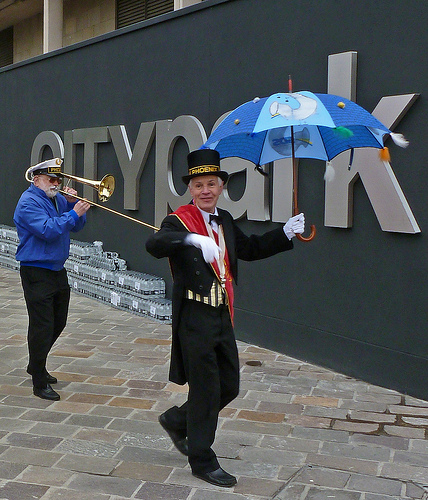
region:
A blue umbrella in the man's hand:
[203, 90, 387, 239]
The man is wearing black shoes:
[159, 402, 232, 483]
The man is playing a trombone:
[25, 163, 166, 229]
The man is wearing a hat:
[30, 157, 64, 175]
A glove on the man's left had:
[285, 211, 306, 234]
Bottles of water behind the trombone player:
[3, 224, 171, 318]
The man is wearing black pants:
[175, 304, 241, 467]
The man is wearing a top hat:
[180, 149, 229, 177]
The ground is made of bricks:
[0, 264, 426, 498]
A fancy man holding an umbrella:
[146, 82, 393, 489]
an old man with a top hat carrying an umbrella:
[138, 71, 411, 489]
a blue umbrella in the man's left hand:
[196, 67, 410, 246]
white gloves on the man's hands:
[184, 212, 308, 265]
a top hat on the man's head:
[180, 148, 231, 183]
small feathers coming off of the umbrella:
[312, 121, 410, 187]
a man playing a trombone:
[12, 155, 170, 404]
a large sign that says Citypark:
[25, 53, 425, 237]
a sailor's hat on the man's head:
[25, 156, 67, 178]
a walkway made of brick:
[1, 263, 427, 498]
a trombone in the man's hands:
[22, 165, 163, 231]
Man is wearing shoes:
[154, 409, 237, 486]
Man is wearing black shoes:
[155, 409, 242, 487]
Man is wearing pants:
[163, 297, 243, 476]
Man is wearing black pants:
[161, 295, 243, 474]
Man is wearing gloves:
[184, 211, 309, 261]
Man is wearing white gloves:
[180, 210, 305, 261]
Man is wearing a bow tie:
[206, 214, 225, 228]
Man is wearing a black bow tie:
[206, 209, 227, 227]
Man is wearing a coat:
[144, 201, 296, 387]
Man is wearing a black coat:
[143, 201, 295, 384]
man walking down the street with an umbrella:
[143, 150, 305, 486]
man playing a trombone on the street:
[11, 156, 89, 401]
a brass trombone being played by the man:
[25, 165, 161, 231]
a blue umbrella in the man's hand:
[200, 74, 409, 243]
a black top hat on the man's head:
[181, 148, 227, 182]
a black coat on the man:
[143, 200, 294, 384]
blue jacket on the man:
[13, 183, 86, 273]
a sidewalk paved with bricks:
[0, 263, 426, 499]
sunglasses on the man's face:
[40, 173, 61, 183]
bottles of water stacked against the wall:
[0, 223, 174, 321]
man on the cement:
[86, 140, 318, 433]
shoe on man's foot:
[193, 452, 244, 498]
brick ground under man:
[254, 415, 350, 497]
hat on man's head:
[180, 144, 233, 186]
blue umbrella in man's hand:
[225, 52, 393, 221]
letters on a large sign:
[16, 106, 393, 242]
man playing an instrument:
[0, 154, 145, 300]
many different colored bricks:
[65, 365, 150, 465]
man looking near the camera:
[139, 131, 308, 311]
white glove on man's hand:
[184, 222, 230, 270]